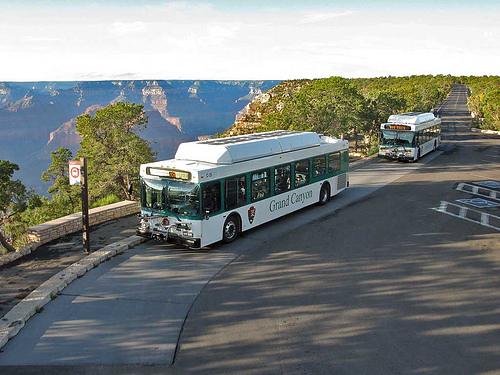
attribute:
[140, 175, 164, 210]
windshield — clean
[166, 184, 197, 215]
windshield — clean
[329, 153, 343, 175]
window — closed, clean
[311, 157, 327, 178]
window — closed, clean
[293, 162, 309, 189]
window — closed, clean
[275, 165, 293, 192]
window — closed, clean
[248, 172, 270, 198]
window — closed, clean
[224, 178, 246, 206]
window — closed, clean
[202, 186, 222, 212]
window — closed, clean